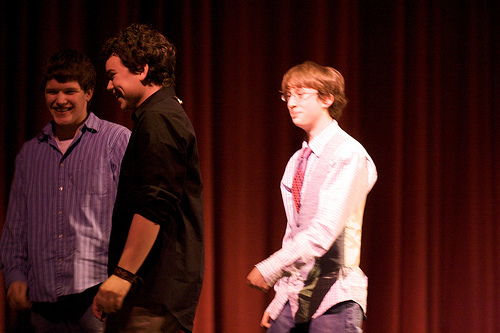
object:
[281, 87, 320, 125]
face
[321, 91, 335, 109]
ear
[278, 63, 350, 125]
head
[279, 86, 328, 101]
glasses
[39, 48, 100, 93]
hair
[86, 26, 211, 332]
boy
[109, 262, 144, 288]
band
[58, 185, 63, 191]
button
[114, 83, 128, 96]
dimple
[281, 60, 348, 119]
hair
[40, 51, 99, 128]
head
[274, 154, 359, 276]
arm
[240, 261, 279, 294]
hand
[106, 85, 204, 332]
black shirt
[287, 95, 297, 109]
nose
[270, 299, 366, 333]
pants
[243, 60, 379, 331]
boy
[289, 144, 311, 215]
red tie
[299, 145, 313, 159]
knot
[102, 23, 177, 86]
curly hair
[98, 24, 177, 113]
head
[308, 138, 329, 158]
collar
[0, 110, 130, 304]
shirt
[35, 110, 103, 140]
collar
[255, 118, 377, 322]
shirt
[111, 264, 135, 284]
wrist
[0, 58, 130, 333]
boy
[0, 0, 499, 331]
curtains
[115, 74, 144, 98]
cheek